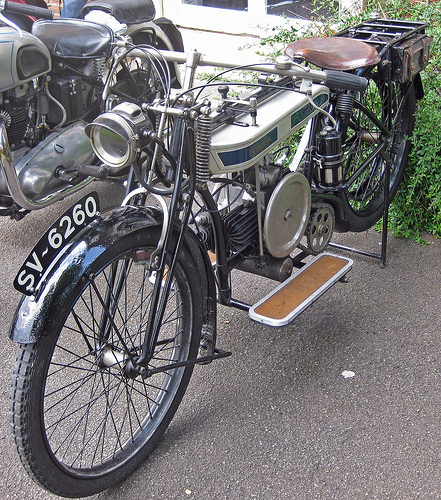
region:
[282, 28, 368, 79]
brown seat of bike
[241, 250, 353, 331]
brown foot stool of bike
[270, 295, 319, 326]
silver boarder of stool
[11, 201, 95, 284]
white numbers on sign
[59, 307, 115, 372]
black spokes on wheel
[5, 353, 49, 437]
black rubber on wheel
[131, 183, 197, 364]
part of black frame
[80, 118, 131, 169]
front light on cycle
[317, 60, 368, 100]
black handle bar on scooter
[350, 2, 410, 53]
black carrying spot on back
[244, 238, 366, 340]
a step on the bike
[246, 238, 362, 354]
the step is tan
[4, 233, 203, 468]
the wheel is black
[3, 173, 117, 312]
the license plate of the bike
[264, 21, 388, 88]
the seat is brown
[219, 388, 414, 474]
the ground is grey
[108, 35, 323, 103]
the handle bars on the bike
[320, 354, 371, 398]
a white spot on the ground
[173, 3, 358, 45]
the window is closed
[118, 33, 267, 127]
wires on the bike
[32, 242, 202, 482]
wheel on the bike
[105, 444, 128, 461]
spoke on the bike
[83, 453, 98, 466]
spoke on the bike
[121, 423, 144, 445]
spoke on the bike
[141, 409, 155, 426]
spoke on the bike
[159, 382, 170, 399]
spoke on the bike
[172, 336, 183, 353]
spoke on the bike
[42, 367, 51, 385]
spoke on the bike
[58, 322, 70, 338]
spoke on the bike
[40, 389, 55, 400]
spoke on the bike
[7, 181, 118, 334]
a plate with SV~6260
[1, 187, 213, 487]
a plate attached to a wheel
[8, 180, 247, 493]
the wheel of a bike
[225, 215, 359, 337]
a step attached to a bike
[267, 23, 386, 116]
a brown seat on a bike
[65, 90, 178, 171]
a light on a bike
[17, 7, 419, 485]
a motorized bike on pavement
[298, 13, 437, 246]
plants behind the back of a wheel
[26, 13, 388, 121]
handlebars on a bike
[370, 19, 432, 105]
a brown pouch to hold items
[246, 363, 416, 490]
The ground is made of asphalt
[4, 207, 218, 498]
The front wheel of the bike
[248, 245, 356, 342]
The step on the bike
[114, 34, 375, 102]
The handle on the bike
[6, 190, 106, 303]
The numbers on the bike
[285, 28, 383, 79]
The seat on the bike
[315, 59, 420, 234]
The back wheel of the bike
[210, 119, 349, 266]
The mechanics to the bike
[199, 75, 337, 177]
The top of the bike is silver